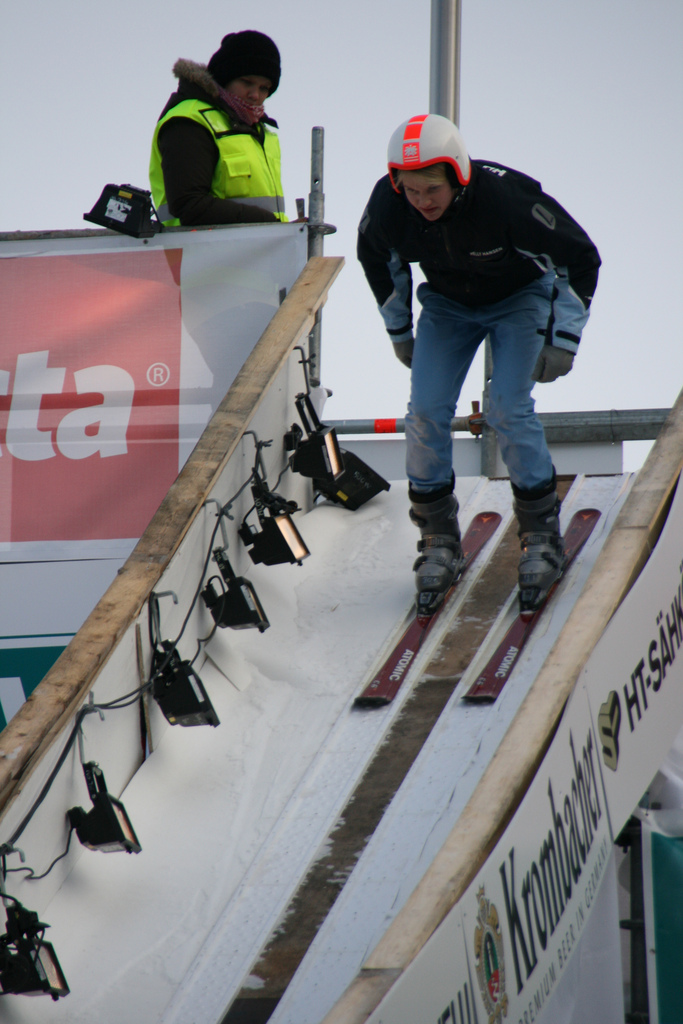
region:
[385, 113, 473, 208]
A helmet on a skier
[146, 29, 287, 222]
A person watching a skier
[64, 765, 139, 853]
A light attached to a wall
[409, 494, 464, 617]
A black ski boot on a foot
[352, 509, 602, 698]
A pair of skis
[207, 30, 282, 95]
A hat on a person's head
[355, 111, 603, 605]
A skier on a ramp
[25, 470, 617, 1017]
A ski ramp with a skier on it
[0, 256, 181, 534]
Part of a hanging sign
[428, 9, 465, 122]
A metal pole behind a skier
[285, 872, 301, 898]
The woman is holding a large orange.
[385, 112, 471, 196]
a white and neon pink helmet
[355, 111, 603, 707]
a skier on platform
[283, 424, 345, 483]
a black spot light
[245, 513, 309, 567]
a black spot light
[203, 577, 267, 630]
a black spot light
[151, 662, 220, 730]
a black spot light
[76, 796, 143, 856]
a black spot light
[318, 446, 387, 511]
a black spot light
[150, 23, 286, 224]
Woman in green vest.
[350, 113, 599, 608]
Man in blue and black jacket.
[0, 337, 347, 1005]
Lights illuminate the ramp.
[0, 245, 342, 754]
Wooden railing on ski ramp.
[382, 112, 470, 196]
White helmet with bright orange stripe.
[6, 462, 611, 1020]
Snow-covered ski ramp.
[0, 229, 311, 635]
White banner with red text.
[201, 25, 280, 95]
Purple winter cap.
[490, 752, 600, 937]
word on a banner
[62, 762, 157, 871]
flood lights on snow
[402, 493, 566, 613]
black pair of ski boots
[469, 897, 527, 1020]
colorful crest emblem on a banner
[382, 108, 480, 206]
an orange and grey helmet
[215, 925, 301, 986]
a rut in the snow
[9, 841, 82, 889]
a crooked black wire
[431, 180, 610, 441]
a man on the skis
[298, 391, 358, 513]
a light on the ramp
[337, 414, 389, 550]
a light on the ramp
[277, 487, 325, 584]
a light on the ramp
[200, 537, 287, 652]
a light on the ramp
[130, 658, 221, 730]
a light on the ramp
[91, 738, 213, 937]
a light on the ramp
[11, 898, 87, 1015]
a light on the ramp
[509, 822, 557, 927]
black letters on the sign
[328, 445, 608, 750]
a pair of skis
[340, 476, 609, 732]
the skis are red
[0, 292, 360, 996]
a row of lights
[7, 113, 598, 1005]
man standing on top of slope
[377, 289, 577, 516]
a pair of jeans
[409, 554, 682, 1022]
banner on the side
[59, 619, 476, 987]
snow on the slope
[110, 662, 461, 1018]
tracks in the snow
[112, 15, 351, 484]
person leaning on railing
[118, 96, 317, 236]
a neon green vest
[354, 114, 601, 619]
man taking off on a ski ramp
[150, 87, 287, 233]
Yellow vest man is wearing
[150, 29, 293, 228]
man wearing a black cap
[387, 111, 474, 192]
orange and white helmet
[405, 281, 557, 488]
blue jeans man is wearing